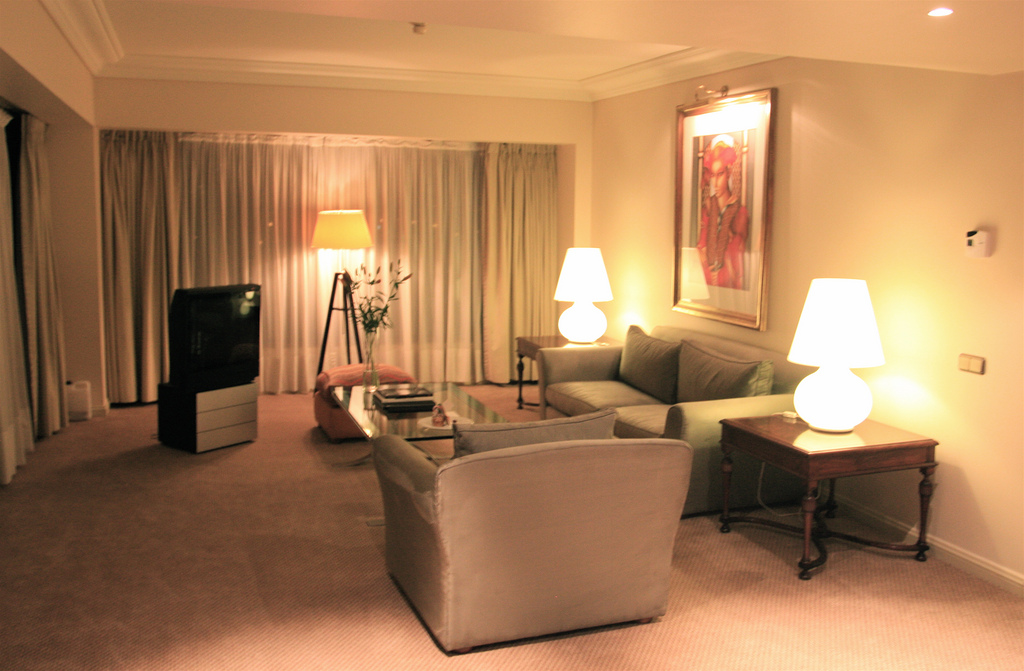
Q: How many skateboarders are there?
A: One.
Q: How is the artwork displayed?
A: In a picture frame.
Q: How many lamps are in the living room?
A: Three lamps.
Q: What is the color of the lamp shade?
A: Is white.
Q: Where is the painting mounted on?
A: The wall.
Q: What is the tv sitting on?
A: Tv stand.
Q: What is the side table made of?
A: Wood.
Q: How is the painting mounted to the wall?
A: Nails.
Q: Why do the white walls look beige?
A: The lighting.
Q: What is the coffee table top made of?
A: Glass.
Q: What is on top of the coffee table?
A: A book.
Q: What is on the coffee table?
A: Flowers.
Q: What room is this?
A: Family room.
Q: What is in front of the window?
A: Lamp and television.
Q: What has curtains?
A: Tall window.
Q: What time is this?
A: Night.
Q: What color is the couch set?
A: Grey.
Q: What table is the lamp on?
A: End table.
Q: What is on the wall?
A: Picture.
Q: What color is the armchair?
A: Grey.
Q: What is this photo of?
A: A living room.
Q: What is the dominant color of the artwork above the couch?
A: Red.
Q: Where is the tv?
A: On the stand.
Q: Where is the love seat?
A: Next to the end table.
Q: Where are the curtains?
A: Covering the window.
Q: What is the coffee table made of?
A: Glass.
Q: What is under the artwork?
A: A couch.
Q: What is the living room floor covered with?
A: Carpet.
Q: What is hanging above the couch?
A: A painting.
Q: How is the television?
A: Off.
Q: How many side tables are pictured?
A: Two.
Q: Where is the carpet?
A: On the floor.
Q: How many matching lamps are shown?
A: Two.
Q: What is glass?
A: Coffee table.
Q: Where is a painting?
A: On the wall.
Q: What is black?
A: TV.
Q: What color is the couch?
A: Gray.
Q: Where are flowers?
A: In a vase.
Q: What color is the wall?
A: White.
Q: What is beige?
A: Carpet.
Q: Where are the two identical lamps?
A: On the end tables.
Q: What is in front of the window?
A: A lamp.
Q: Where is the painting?
A: Over the couch.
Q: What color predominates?
A: Beige.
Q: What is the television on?
A: A stand.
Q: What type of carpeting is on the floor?
A: Wall-to-wall.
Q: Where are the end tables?
A: On either side of the sofa.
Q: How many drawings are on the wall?
A: One.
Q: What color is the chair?
A: Tan.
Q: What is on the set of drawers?
A: A television.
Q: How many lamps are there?
A: Three.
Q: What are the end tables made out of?
A: Wood.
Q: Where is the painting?
A: Hanging on the wall over the couch.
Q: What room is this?
A: A living room.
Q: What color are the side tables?
A: Brown.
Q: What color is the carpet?
A: Beige.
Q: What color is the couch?
A: Grey.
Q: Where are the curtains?
A: Covering the windows.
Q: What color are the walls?
A: White.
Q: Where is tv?
A: On tv stand.